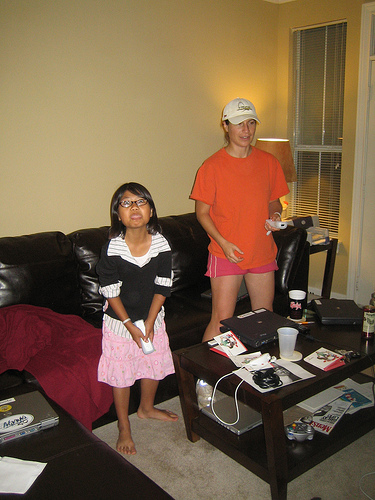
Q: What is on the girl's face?
A: Glasses.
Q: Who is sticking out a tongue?
A: The girl on the left.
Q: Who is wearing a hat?
A: The woman on the right.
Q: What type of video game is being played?
A: Wii.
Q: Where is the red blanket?
A: On the sofa.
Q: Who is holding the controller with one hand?
A: The woman on the right.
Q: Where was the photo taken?
A: In a living room.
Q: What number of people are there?
A: Two.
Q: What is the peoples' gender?
A: Female.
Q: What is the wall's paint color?
A: Beige.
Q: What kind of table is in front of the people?
A: A coffee table.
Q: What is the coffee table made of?
A: Wood.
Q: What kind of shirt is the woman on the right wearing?
A: A t-shirt.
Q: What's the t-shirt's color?
A: Orange.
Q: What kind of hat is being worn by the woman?
A: A cap.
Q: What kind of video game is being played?
A: Wii.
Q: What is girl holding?
A: Controller.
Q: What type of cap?
A: Ball.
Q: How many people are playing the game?
A: 2.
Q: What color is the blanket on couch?
A: Red.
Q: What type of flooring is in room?
A: Carpet.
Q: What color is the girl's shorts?
A: Pink.